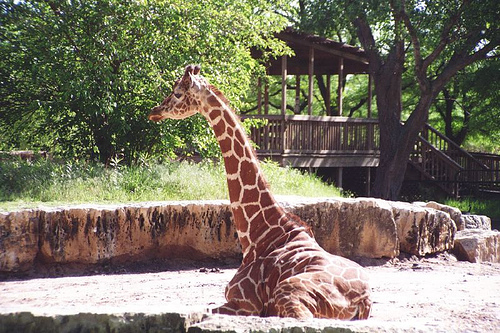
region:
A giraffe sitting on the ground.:
[147, 39, 389, 331]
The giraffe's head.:
[137, 58, 222, 136]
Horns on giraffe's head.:
[170, 50, 206, 80]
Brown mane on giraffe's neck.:
[203, 76, 288, 196]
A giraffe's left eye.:
[166, 81, 188, 107]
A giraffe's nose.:
[140, 97, 175, 133]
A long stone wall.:
[3, 183, 493, 284]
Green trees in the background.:
[3, 0, 493, 195]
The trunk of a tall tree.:
[303, 3, 473, 198]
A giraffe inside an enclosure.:
[121, 57, 373, 331]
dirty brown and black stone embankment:
[2, 194, 467, 268]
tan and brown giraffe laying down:
[144, 60, 381, 327]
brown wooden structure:
[222, 19, 498, 204]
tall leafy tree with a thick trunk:
[300, 1, 499, 198]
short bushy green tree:
[2, 1, 298, 208]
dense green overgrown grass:
[2, 156, 350, 205]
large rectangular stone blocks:
[0, 299, 427, 331]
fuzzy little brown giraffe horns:
[181, 60, 204, 78]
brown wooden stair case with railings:
[390, 113, 490, 203]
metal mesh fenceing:
[308, 162, 498, 207]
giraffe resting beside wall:
[145, 59, 377, 319]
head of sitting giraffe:
[146, 62, 210, 121]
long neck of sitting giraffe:
[203, 102, 290, 233]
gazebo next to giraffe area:
[252, 25, 404, 163]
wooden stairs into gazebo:
[411, 122, 491, 202]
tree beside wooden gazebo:
[10, 0, 302, 168]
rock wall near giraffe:
[4, 196, 236, 271]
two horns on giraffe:
[183, 61, 202, 73]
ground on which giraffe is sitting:
[374, 262, 499, 330]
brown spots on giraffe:
[231, 165, 298, 250]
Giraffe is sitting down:
[146, 62, 379, 325]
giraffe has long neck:
[141, 64, 318, 253]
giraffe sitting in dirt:
[8, 248, 498, 330]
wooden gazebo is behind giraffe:
[208, 28, 410, 160]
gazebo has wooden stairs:
[399, 113, 488, 201]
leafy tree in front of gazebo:
[309, 3, 497, 201]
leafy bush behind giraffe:
[7, 0, 294, 161]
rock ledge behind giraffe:
[1, 200, 461, 265]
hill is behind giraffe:
[0, 160, 340, 205]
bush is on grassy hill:
[6, 39, 346, 204]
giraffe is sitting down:
[134, 47, 352, 311]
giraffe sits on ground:
[160, 73, 338, 328]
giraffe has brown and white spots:
[177, 75, 365, 313]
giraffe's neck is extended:
[132, 54, 326, 305]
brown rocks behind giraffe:
[3, 198, 408, 263]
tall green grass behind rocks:
[18, 149, 335, 203]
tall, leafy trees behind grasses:
[7, 23, 289, 178]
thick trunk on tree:
[325, 32, 449, 185]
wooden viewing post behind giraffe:
[223, 3, 473, 217]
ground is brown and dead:
[23, 268, 270, 311]